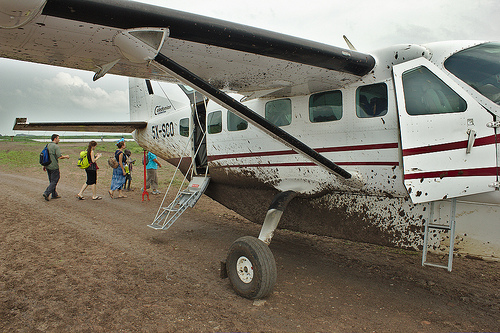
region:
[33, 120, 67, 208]
A man with a blue backpack.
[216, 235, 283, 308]
A large airplane tire.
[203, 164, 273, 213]
Dirt splattered onto the side of an aircraft.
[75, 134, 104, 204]
A woman with a yellow backpack.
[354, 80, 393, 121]
A plane passenger window.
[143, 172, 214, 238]
A ladder protruding from the side of the aircraft.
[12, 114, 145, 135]
The rear fin of an airplane.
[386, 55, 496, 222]
An open cockpit door.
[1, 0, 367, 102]
A small airplane wing.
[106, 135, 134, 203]
A woman in a blue dress, walking next to a child.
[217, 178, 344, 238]
mud splatters on bottom of plane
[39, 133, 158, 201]
group of people walking behind plane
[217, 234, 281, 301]
wheel on the back of plane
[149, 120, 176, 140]
black letters and numbers on the back of plane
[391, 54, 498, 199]
front door of red and white plane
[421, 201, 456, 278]
ladder hanging from the front door of plane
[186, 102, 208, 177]
back door of plane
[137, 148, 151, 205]
red stand under the back of the plane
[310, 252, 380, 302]
ground is brown and muddy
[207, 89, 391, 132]
five windows between the doors of the plane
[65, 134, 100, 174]
woman wearing green backpack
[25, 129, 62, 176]
man carrying blue bag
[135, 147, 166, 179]
man's shirt is blue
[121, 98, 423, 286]
mud on the plane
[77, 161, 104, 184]
woman wearing a skirt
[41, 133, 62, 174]
man's shirt is gray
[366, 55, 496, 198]
plane door is open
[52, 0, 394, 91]
plane's wing is black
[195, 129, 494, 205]
red line on plane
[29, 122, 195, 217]
people walking behind plane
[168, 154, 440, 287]
a muddy side of a plane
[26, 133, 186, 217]
a group of tourists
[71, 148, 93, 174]
a neon green backpack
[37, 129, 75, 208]
a man with a blue backpack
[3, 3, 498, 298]
a very small plane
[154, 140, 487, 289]
mud splattered on the side of a plane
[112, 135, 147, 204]
a woman in a blue skirt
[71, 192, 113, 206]
flip flops on a woman's feet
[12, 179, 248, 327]
a dirt runway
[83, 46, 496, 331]
a white plane with red stripes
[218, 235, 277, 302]
Wheel of an airplane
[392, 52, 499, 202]
Door of an airplane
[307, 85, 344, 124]
Window on an airplane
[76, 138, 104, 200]
Woman wearing a yellow backpack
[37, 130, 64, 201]
Man wearing a blue backpack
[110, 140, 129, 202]
Woman wearing a blue skirt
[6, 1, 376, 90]
Wing of an airplane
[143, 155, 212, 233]
Steps from an airplane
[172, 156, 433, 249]
Dirt on the side of airplane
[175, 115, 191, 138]
Window of an airplane